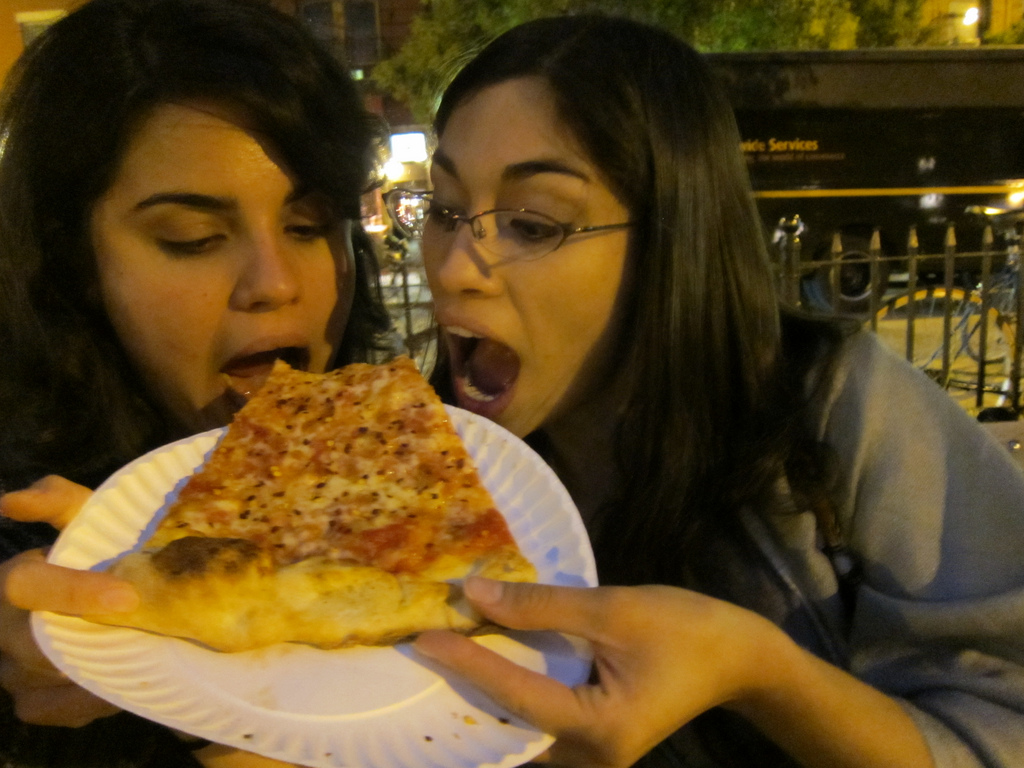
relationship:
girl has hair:
[418, 19, 1023, 763] [439, 19, 792, 549]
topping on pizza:
[149, 521, 305, 576] [43, 359, 551, 651]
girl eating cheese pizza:
[3, 3, 440, 762] [100, 358, 532, 647]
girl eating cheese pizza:
[418, 19, 1023, 763] [100, 358, 532, 647]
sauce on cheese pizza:
[343, 504, 434, 565] [100, 358, 532, 647]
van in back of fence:
[686, 39, 993, 284] [779, 214, 993, 416]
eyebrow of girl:
[127, 186, 249, 219] [3, 3, 440, 762]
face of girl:
[414, 115, 589, 450] [418, 19, 1023, 763]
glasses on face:
[375, 180, 628, 267] [414, 115, 589, 450]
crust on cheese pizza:
[90, 558, 542, 654] [100, 358, 532, 647]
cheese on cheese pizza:
[263, 435, 439, 533] [100, 358, 532, 647]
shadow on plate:
[490, 634, 592, 689] [31, 398, 611, 764]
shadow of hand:
[490, 634, 592, 689] [405, 579, 784, 765]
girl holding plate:
[0, 0, 373, 763] [31, 398, 611, 764]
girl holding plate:
[418, 19, 1023, 763] [31, 398, 611, 764]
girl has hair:
[418, 19, 1023, 763] [430, 18, 845, 597]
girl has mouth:
[418, 19, 1023, 763] [426, 309, 524, 420]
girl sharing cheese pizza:
[418, 19, 1023, 763] [100, 358, 532, 647]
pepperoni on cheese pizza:
[452, 498, 515, 563] [100, 358, 532, 647]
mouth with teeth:
[430, 310, 521, 416] [441, 325, 485, 343]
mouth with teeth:
[430, 310, 521, 416] [452, 376, 504, 409]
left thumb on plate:
[464, 575, 610, 645] [31, 398, 611, 764]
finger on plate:
[411, 627, 595, 746] [31, 398, 611, 764]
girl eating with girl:
[418, 19, 1023, 763] [0, 0, 373, 763]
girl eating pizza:
[418, 19, 1023, 763] [115, 353, 533, 654]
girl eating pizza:
[0, 0, 373, 763] [115, 353, 533, 654]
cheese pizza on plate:
[100, 358, 532, 647] [31, 398, 611, 764]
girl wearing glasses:
[418, 19, 1023, 763] [379, 191, 641, 265]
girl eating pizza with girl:
[418, 19, 1023, 763] [0, 0, 373, 763]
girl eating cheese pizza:
[0, 0, 373, 763] [100, 358, 532, 647]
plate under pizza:
[31, 398, 611, 764] [115, 353, 533, 654]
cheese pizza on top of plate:
[100, 358, 532, 647] [31, 398, 611, 764]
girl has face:
[418, 19, 1023, 763] [418, 83, 615, 438]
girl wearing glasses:
[418, 19, 1023, 763] [385, 189, 640, 262]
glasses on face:
[385, 189, 640, 262] [418, 83, 615, 438]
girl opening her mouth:
[0, 0, 373, 763] [214, 335, 321, 405]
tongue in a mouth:
[460, 339, 519, 402] [423, 309, 545, 428]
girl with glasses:
[415, 26, 1021, 763] [389, 172, 631, 276]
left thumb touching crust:
[452, 566, 593, 640] [86, 564, 537, 654]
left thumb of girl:
[452, 566, 593, 640] [418, 19, 1023, 763]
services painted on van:
[758, 131, 828, 157] [690, 50, 1024, 315]